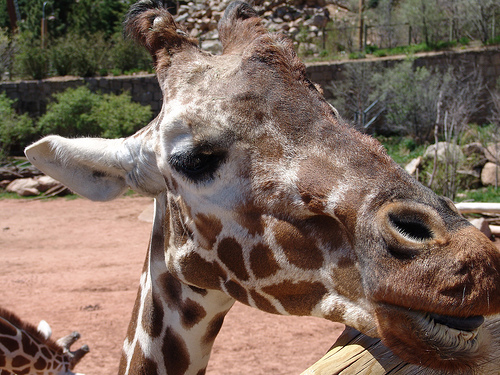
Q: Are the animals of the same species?
A: Yes, all the animals are giraffes.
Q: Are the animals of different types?
A: No, all the animals are giraffes.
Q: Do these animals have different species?
A: No, all the animals are giraffes.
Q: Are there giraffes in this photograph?
A: Yes, there is a giraffe.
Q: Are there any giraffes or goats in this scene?
A: Yes, there is a giraffe.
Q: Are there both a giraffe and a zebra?
A: No, there is a giraffe but no zebras.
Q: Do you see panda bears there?
A: No, there are no panda bears.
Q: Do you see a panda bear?
A: No, there are no panda bears.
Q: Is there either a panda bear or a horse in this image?
A: No, there are no panda bears or horses.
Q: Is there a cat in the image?
A: No, there are no cats.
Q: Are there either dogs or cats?
A: No, there are no cats or dogs.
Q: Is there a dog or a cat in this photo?
A: No, there are no cats or dogs.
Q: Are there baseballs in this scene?
A: No, there are no baseballs.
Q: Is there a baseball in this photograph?
A: No, there are no baseballs.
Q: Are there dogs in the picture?
A: No, there are no dogs.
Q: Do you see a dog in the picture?
A: No, there are no dogs.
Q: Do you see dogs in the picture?
A: No, there are no dogs.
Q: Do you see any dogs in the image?
A: No, there are no dogs.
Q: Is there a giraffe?
A: Yes, there is a giraffe.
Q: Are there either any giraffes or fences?
A: Yes, there is a giraffe.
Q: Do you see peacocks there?
A: No, there are no peacocks.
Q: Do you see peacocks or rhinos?
A: No, there are no peacocks or rhinos.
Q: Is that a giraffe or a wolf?
A: That is a giraffe.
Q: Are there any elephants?
A: No, there are no elephants.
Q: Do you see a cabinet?
A: No, there are no cabinets.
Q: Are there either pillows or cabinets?
A: No, there are no cabinets or pillows.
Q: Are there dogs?
A: No, there are no dogs.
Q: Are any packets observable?
A: No, there are no packets.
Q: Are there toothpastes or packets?
A: No, there are no packets or toothpastes.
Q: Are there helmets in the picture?
A: No, there are no helmets.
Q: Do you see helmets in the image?
A: No, there are no helmets.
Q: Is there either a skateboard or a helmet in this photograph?
A: No, there are no helmets or skateboards.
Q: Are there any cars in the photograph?
A: No, there are no cars.